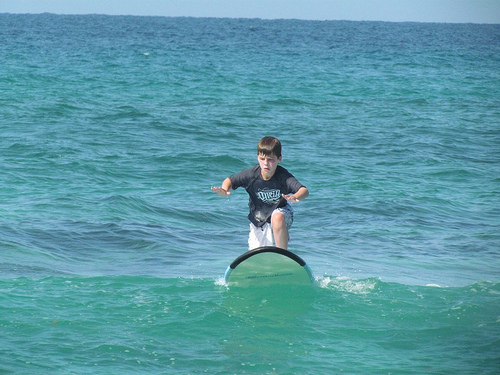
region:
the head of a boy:
[253, 132, 288, 182]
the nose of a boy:
[262, 155, 269, 167]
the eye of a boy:
[257, 155, 266, 162]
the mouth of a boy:
[261, 164, 271, 173]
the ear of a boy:
[275, 151, 285, 163]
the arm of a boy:
[281, 169, 311, 203]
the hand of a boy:
[276, 190, 302, 210]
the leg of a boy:
[271, 204, 296, 251]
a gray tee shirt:
[226, 160, 307, 230]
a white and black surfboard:
[212, 239, 327, 312]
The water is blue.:
[3, 13, 498, 370]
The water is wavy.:
[3, 15, 498, 371]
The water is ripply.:
[0, 15, 499, 372]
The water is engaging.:
[0, 16, 499, 371]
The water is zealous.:
[1, 17, 497, 374]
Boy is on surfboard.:
[196, 122, 333, 309]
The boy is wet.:
[191, 85, 341, 337]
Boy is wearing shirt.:
[193, 120, 343, 316]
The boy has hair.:
[183, 86, 340, 330]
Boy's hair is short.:
[181, 127, 338, 317]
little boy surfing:
[191, 116, 360, 312]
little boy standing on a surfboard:
[198, 116, 338, 308]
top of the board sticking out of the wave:
[198, 236, 332, 291]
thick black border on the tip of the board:
[219, 246, 323, 273]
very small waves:
[8, 262, 489, 323]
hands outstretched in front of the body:
[206, 179, 321, 206]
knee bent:
[266, 200, 292, 243]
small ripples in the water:
[345, 138, 445, 189]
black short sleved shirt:
[227, 164, 304, 225]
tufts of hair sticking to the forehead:
[257, 148, 270, 158]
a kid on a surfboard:
[205, 124, 330, 308]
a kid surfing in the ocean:
[193, 91, 341, 341]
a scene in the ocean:
[10, 5, 498, 363]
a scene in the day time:
[4, 7, 495, 372]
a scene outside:
[15, 11, 487, 352]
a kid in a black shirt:
[208, 121, 325, 288]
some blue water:
[7, 7, 497, 284]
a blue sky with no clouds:
[15, 2, 499, 38]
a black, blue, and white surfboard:
[220, 243, 318, 290]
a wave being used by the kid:
[14, 263, 498, 365]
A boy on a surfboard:
[187, 81, 341, 329]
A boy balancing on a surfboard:
[187, 118, 342, 307]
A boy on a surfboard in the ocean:
[185, 106, 360, 315]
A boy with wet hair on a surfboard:
[175, 104, 330, 321]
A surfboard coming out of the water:
[220, 231, 343, 297]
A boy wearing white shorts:
[228, 124, 306, 259]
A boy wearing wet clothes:
[201, 131, 334, 311]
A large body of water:
[23, 8, 478, 373]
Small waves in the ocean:
[28, 3, 490, 306]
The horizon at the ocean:
[6, 1, 498, 33]